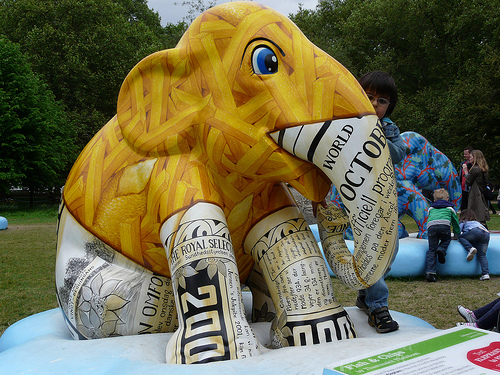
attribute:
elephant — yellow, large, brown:
[89, 10, 387, 338]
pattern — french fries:
[165, 62, 244, 171]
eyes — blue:
[236, 39, 284, 77]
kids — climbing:
[401, 157, 496, 271]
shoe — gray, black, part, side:
[370, 305, 396, 334]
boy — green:
[352, 69, 418, 213]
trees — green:
[1, 18, 155, 219]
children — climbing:
[406, 179, 500, 270]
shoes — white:
[469, 248, 490, 281]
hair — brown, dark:
[365, 77, 392, 94]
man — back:
[458, 137, 469, 181]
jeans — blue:
[372, 266, 401, 313]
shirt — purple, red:
[460, 220, 483, 233]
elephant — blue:
[385, 134, 442, 221]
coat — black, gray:
[474, 172, 489, 198]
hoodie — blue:
[427, 200, 455, 225]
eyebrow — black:
[245, 29, 279, 47]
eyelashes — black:
[248, 46, 257, 80]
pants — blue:
[474, 299, 499, 330]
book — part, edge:
[494, 283, 500, 300]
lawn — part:
[6, 203, 74, 338]